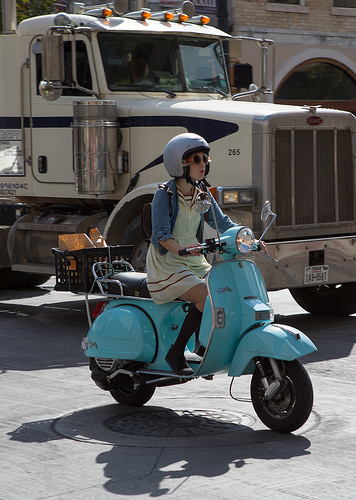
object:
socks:
[168, 305, 204, 356]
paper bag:
[59, 227, 108, 251]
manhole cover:
[101, 406, 257, 438]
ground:
[165, 449, 235, 469]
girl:
[145, 133, 268, 376]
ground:
[327, 341, 348, 375]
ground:
[35, 359, 69, 398]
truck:
[0, 7, 356, 316]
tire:
[250, 353, 314, 432]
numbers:
[228, 149, 241, 156]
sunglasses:
[183, 154, 211, 166]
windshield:
[97, 34, 230, 94]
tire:
[109, 386, 156, 406]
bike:
[80, 191, 318, 434]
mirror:
[195, 191, 211, 214]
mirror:
[261, 200, 272, 221]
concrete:
[0, 313, 356, 498]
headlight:
[236, 227, 256, 254]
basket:
[51, 244, 134, 292]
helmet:
[163, 132, 211, 179]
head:
[163, 132, 211, 181]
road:
[0, 270, 330, 498]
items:
[58, 227, 107, 269]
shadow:
[6, 403, 311, 497]